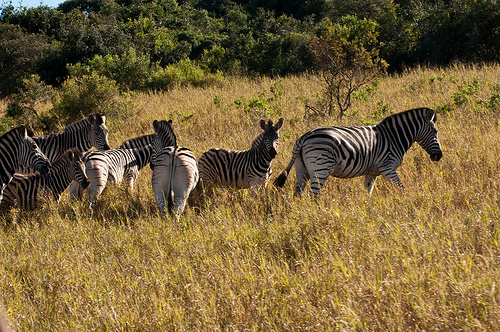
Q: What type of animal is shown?
A: Zebras.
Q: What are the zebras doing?
A: Walking.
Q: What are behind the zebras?
A: Bushes.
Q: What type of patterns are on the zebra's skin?
A: Black and white.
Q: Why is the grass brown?
A: Lack of water.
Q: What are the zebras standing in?
A: Grass.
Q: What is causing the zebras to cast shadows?
A: The sun.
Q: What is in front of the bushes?
A: Zebras.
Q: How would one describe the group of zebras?
A: It is a herd.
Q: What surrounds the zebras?
A: Grass.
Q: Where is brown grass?
A: Around zebras.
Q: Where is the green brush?
A: In background.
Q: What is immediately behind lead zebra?
A: Small tree.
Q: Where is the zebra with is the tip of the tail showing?
A: On the right.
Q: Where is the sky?
A: Upper left.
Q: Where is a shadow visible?
A: Left of fifth zebra.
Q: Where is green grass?
A: Mixed in brown grass.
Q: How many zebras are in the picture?
A: 7.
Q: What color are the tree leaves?
A: Green.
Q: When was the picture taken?
A: Daytime.